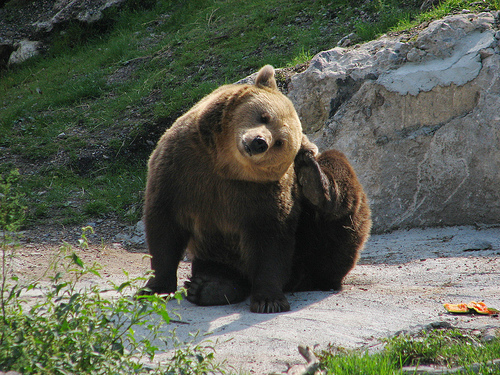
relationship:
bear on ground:
[133, 65, 376, 314] [62, 273, 446, 359]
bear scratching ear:
[133, 65, 376, 314] [253, 58, 280, 87]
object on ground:
[415, 277, 498, 319] [0, 260, 473, 371]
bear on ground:
[0, 59, 395, 320] [398, 125, 462, 185]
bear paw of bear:
[251, 291, 290, 314] [91, 56, 381, 338]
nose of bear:
[252, 137, 268, 151] [133, 65, 376, 314]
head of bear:
[216, 64, 303, 181] [133, 65, 376, 314]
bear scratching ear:
[133, 65, 376, 314] [253, 64, 278, 89]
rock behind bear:
[326, 17, 498, 235] [133, 65, 376, 314]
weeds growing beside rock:
[4, 161, 134, 227] [304, 8, 499, 143]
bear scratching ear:
[133, 65, 376, 314] [289, 132, 323, 167]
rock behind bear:
[287, 17, 499, 235] [175, 99, 365, 261]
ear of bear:
[255, 57, 282, 86] [111, 85, 403, 339]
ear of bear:
[295, 130, 329, 170] [111, 85, 403, 339]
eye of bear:
[257, 111, 277, 127] [133, 65, 376, 314]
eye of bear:
[273, 131, 289, 151] [133, 65, 376, 314]